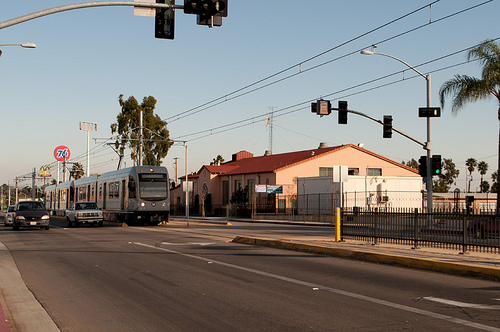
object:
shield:
[137, 170, 171, 202]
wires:
[0, 48, 481, 183]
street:
[0, 215, 496, 331]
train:
[45, 165, 171, 225]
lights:
[320, 101, 328, 115]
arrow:
[162, 234, 221, 252]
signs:
[255, 185, 284, 194]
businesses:
[185, 156, 301, 216]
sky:
[0, 0, 497, 191]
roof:
[179, 143, 420, 179]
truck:
[65, 200, 104, 227]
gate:
[343, 176, 385, 257]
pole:
[332, 205, 342, 241]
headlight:
[140, 202, 146, 207]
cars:
[13, 198, 53, 233]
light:
[434, 156, 441, 174]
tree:
[437, 53, 499, 206]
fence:
[337, 206, 499, 258]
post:
[419, 73, 434, 227]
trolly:
[114, 169, 186, 233]